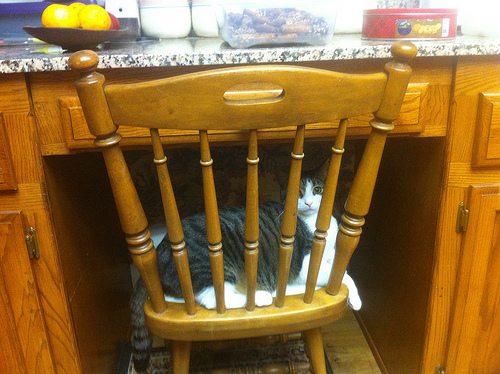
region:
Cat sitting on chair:
[156, 170, 311, 300]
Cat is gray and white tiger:
[85, 92, 362, 299]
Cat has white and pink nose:
[302, 194, 312, 219]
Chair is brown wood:
[65, 82, 429, 317]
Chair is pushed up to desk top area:
[26, 25, 479, 284]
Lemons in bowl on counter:
[47, 4, 145, 59]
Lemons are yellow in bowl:
[28, 10, 146, 55]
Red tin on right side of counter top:
[356, 12, 476, 88]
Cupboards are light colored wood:
[11, 96, 92, 298]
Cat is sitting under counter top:
[126, 105, 381, 306]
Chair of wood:
[55, 16, 424, 373]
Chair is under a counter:
[59, 35, 418, 371]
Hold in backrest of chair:
[211, 71, 293, 110]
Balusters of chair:
[155, 132, 334, 306]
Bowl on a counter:
[21, 27, 136, 60]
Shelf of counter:
[421, 66, 499, 368]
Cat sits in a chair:
[98, 157, 368, 372]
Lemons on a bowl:
[37, 1, 116, 30]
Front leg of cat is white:
[303, 247, 369, 314]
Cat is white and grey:
[100, 160, 372, 372]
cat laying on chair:
[136, 161, 398, 320]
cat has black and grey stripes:
[100, 172, 427, 351]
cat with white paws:
[98, 152, 437, 354]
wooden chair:
[62, 38, 419, 372]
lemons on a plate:
[23, 2, 139, 52]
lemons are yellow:
[23, 3, 137, 46]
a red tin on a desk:
[356, 5, 476, 48]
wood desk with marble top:
[11, 35, 450, 355]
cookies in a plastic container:
[211, 6, 353, 52]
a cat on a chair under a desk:
[25, 87, 477, 372]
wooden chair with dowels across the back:
[52, 48, 418, 338]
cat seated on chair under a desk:
[101, 162, 381, 357]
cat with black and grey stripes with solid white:
[120, 155, 371, 355]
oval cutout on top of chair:
[205, 50, 307, 135]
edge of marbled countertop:
[10, 25, 487, 75]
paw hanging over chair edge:
[315, 225, 371, 330]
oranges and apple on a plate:
[16, 1, 123, 53]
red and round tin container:
[351, 0, 461, 46]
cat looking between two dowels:
[273, 165, 338, 223]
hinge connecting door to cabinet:
[446, 170, 473, 255]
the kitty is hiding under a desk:
[121, 170, 369, 370]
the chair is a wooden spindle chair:
[63, 40, 416, 370]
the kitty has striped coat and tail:
[127, 161, 362, 371]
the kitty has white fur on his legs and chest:
[186, 175, 363, 313]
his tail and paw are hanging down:
[125, 266, 365, 366]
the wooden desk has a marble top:
[5, 25, 497, 365]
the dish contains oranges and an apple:
[17, 0, 127, 48]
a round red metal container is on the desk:
[358, 6, 459, 38]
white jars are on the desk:
[140, 1, 237, 37]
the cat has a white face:
[293, 181, 326, 218]